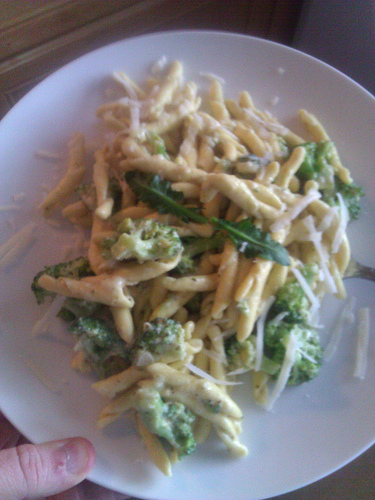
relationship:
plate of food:
[0, 31, 373, 499] [4, 56, 358, 478]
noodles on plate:
[41, 64, 347, 325] [0, 31, 373, 499]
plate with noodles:
[0, 31, 373, 499] [41, 64, 347, 325]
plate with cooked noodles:
[0, 31, 373, 499] [41, 64, 347, 325]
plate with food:
[0, 31, 373, 499] [4, 56, 358, 478]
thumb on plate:
[0, 440, 94, 499] [0, 31, 373, 499]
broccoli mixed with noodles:
[143, 321, 182, 357] [41, 64, 347, 325]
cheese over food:
[32, 60, 355, 448] [4, 56, 358, 478]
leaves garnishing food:
[126, 171, 289, 263] [4, 56, 358, 478]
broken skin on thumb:
[53, 456, 68, 475] [0, 440, 94, 499]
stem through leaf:
[135, 179, 178, 211] [127, 171, 205, 226]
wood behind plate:
[0, 1, 306, 453] [0, 31, 373, 499]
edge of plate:
[268, 41, 373, 101] [0, 31, 373, 499]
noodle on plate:
[39, 132, 88, 210] [0, 31, 373, 499]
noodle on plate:
[301, 110, 353, 186] [0, 31, 373, 499]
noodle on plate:
[37, 275, 135, 309] [0, 31, 373, 499]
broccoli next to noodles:
[143, 321, 182, 357] [41, 64, 347, 325]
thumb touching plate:
[0, 440, 94, 499] [0, 31, 373, 499]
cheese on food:
[32, 60, 355, 448] [4, 56, 358, 478]